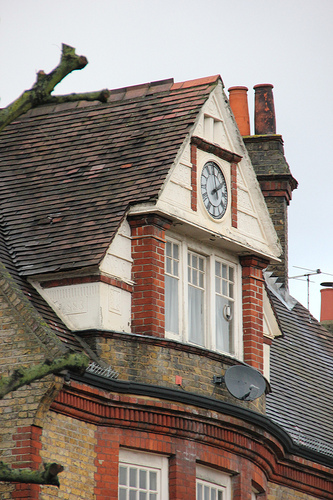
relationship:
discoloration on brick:
[168, 416, 207, 467] [159, 407, 213, 478]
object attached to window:
[223, 304, 232, 320] [214, 254, 238, 358]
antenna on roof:
[287, 261, 319, 308] [265, 294, 331, 450]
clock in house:
[199, 158, 230, 223] [0, 72, 333, 498]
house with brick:
[14, 77, 321, 498] [127, 264, 159, 289]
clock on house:
[198, 162, 231, 224] [9, 40, 331, 470]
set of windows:
[163, 234, 240, 344] [160, 231, 248, 357]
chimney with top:
[252, 81, 278, 132] [20, 63, 228, 307]